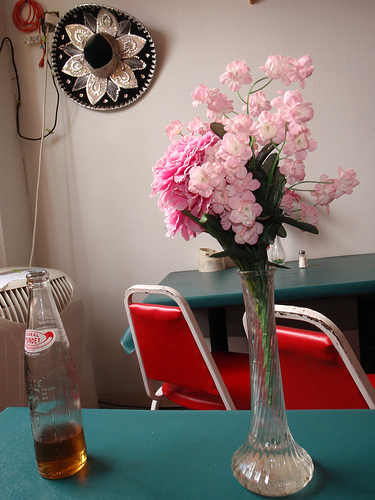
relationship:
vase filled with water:
[231, 267, 316, 497] [230, 428, 316, 497]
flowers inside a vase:
[150, 54, 361, 270] [231, 267, 316, 497]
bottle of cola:
[23, 272, 89, 480] [30, 420, 88, 479]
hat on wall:
[51, 3, 157, 111] [2, 1, 375, 409]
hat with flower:
[51, 3, 157, 111] [61, 8, 147, 106]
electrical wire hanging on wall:
[0, 2, 60, 142] [2, 1, 375, 409]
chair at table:
[123, 286, 250, 411] [120, 253, 374, 373]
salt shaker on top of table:
[297, 249, 308, 270] [120, 253, 374, 373]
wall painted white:
[2, 1, 375, 409] [77, 157, 130, 233]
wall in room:
[2, 1, 375, 409] [0, 0, 374, 499]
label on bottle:
[24, 329, 56, 354] [23, 272, 89, 480]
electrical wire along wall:
[0, 2, 60, 142] [2, 1, 375, 409]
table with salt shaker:
[120, 253, 374, 373] [297, 249, 308, 270]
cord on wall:
[11, 0, 45, 68] [2, 1, 375, 409]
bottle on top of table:
[23, 272, 89, 480] [120, 253, 374, 373]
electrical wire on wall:
[0, 2, 60, 142] [2, 1, 375, 409]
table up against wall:
[120, 253, 374, 373] [2, 1, 375, 409]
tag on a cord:
[23, 34, 42, 47] [11, 0, 45, 68]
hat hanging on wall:
[51, 3, 157, 111] [2, 1, 375, 409]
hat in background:
[51, 3, 157, 111] [0, 0, 374, 113]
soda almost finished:
[30, 420, 88, 479] [27, 364, 76, 431]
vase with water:
[231, 267, 316, 497] [230, 428, 316, 497]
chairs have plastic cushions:
[123, 283, 374, 411] [123, 304, 374, 409]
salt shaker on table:
[297, 249, 308, 270] [120, 253, 374, 373]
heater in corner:
[1, 268, 99, 408] [1, 2, 13, 407]